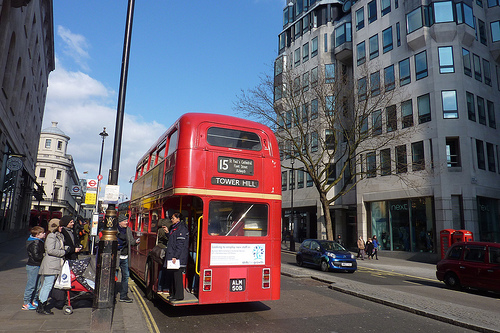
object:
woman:
[163, 212, 191, 301]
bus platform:
[158, 290, 200, 304]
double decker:
[128, 112, 283, 308]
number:
[220, 159, 223, 170]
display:
[217, 156, 254, 176]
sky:
[41, 0, 283, 204]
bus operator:
[162, 212, 190, 302]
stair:
[156, 288, 198, 307]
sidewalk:
[282, 238, 445, 283]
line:
[129, 278, 160, 333]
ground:
[126, 270, 497, 333]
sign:
[210, 242, 266, 265]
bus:
[128, 112, 283, 308]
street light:
[89, 126, 107, 256]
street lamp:
[92, 0, 135, 310]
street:
[126, 270, 497, 330]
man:
[157, 217, 174, 291]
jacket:
[164, 220, 189, 269]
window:
[442, 90, 460, 118]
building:
[274, 0, 496, 264]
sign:
[87, 179, 98, 189]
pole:
[89, 136, 105, 255]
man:
[115, 215, 141, 304]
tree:
[231, 51, 447, 247]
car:
[435, 242, 500, 293]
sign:
[104, 185, 120, 201]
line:
[129, 285, 152, 332]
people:
[61, 215, 83, 305]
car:
[295, 239, 357, 273]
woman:
[35, 218, 74, 316]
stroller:
[61, 249, 96, 314]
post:
[92, 0, 135, 328]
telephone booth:
[439, 228, 456, 260]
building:
[350, 0, 500, 264]